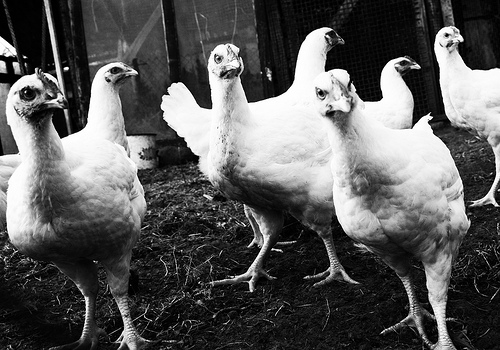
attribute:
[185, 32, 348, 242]
chicken — white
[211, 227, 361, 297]
feet — chicken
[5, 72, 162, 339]
chicken — white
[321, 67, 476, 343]
chicken — white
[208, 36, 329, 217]
chicken — white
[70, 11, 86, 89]
metal pole — tall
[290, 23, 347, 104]
chiclen — white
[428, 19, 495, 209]
chicken — white